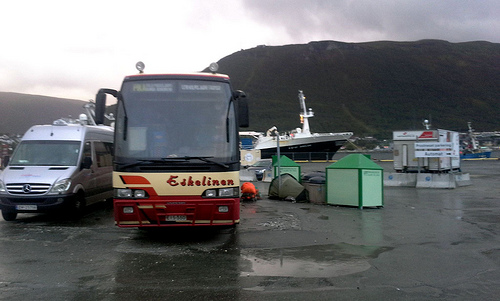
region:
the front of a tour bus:
[109, 64, 244, 227]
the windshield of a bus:
[124, 81, 225, 166]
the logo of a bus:
[165, 170, 233, 189]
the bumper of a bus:
[113, 198, 242, 227]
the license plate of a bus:
[159, 213, 193, 225]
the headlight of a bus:
[113, 183, 145, 195]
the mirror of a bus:
[87, 88, 117, 125]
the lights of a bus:
[131, 55, 147, 76]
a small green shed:
[321, 146, 385, 208]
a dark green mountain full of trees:
[315, 34, 441, 111]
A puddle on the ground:
[241, 240, 391, 277]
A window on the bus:
[118, 81, 234, 161]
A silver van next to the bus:
[3, 123, 114, 216]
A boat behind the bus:
[240, 89, 352, 159]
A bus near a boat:
[93, 60, 250, 229]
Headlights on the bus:
[116, 187, 236, 197]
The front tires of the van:
[1, 190, 88, 218]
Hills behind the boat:
[0, 41, 499, 133]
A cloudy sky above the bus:
[0, 1, 498, 104]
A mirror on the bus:
[234, 94, 248, 126]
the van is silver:
[5, 105, 109, 270]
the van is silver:
[5, 105, 89, 230]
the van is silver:
[2, 102, 115, 236]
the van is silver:
[2, 98, 122, 243]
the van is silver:
[2, 99, 107, 236]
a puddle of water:
[205, 224, 399, 299]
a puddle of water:
[248, 237, 398, 299]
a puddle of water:
[216, 215, 381, 296]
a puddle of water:
[244, 225, 394, 298]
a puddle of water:
[242, 241, 333, 296]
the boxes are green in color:
[321, 139, 398, 210]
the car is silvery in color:
[14, 126, 112, 216]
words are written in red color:
[174, 165, 246, 197]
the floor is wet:
[264, 221, 393, 271]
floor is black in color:
[298, 232, 440, 284]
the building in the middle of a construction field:
[403, 111, 480, 178]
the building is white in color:
[386, 125, 476, 180]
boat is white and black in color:
[280, 105, 331, 140]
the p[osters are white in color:
[416, 139, 461, 158]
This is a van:
[1, 107, 126, 232]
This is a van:
[11, 105, 119, 218]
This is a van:
[10, 100, 135, 243]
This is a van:
[106, 45, 272, 228]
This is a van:
[1, 85, 118, 236]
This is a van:
[5, 101, 131, 251]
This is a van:
[95, 50, 271, 245]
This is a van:
[5, 95, 147, 237]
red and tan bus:
[104, 65, 249, 240]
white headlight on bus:
[197, 181, 243, 206]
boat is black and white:
[256, 87, 353, 159]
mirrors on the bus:
[94, 81, 254, 137]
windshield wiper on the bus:
[165, 146, 232, 169]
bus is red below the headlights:
[121, 191, 248, 235]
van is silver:
[2, 117, 108, 220]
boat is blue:
[456, 152, 498, 159]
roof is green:
[326, 152, 378, 173]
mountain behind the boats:
[210, 33, 499, 147]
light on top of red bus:
[202, 59, 227, 86]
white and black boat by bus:
[95, 58, 361, 242]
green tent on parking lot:
[320, 146, 389, 233]